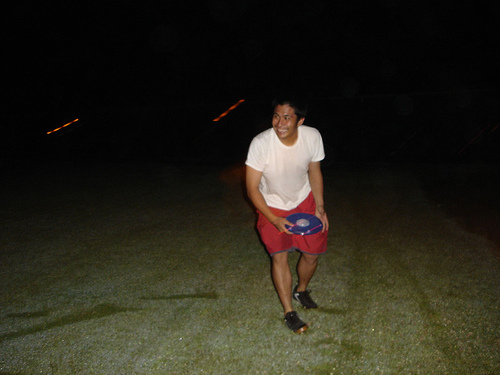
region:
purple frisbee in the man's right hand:
[283, 213, 325, 235]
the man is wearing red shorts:
[255, 194, 323, 259]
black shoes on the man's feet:
[282, 287, 315, 332]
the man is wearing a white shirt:
[243, 124, 323, 211]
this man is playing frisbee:
[246, 99, 330, 336]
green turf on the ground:
[0, 160, 497, 372]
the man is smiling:
[270, 102, 300, 138]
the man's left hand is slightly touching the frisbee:
[301, 147, 329, 235]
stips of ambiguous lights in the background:
[36, 92, 253, 141]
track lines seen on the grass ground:
[4, 198, 477, 371]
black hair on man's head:
[270, 97, 310, 110]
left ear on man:
[296, 113, 304, 126]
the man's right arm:
[242, 151, 287, 231]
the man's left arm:
[309, 130, 333, 230]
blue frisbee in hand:
[286, 205, 321, 235]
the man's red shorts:
[259, 201, 325, 261]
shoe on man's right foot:
[285, 307, 305, 338]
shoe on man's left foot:
[296, 286, 318, 309]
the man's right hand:
[273, 218, 293, 236]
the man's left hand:
[312, 206, 336, 235]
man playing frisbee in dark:
[243, 93, 331, 335]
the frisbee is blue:
[278, 212, 323, 236]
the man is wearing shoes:
[277, 286, 317, 335]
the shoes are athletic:
[279, 287, 319, 336]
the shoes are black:
[280, 287, 318, 333]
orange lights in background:
[42, 94, 245, 134]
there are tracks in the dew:
[8, 289, 359, 371]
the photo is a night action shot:
[1, 0, 498, 374]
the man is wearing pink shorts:
[255, 196, 332, 258]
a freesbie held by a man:
[258, 200, 341, 247]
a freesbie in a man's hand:
[238, 181, 338, 241]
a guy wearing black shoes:
[249, 296, 326, 327]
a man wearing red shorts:
[227, 192, 297, 262]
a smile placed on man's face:
[245, 108, 317, 153]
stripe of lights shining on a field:
[32, 98, 255, 148]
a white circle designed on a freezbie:
[243, 206, 363, 265]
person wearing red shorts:
[257, 208, 324, 255]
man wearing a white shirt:
[240, 128, 332, 221]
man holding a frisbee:
[276, 203, 329, 240]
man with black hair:
[265, 98, 312, 135]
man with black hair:
[272, 106, 292, 121]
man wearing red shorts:
[251, 190, 328, 255]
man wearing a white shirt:
[245, 129, 330, 206]